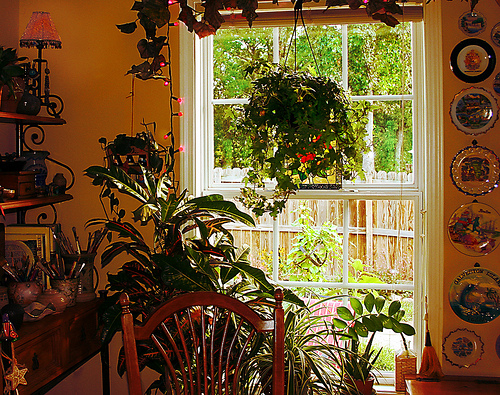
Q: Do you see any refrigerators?
A: No, there are no refrigerators.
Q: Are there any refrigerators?
A: No, there are no refrigerators.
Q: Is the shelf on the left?
A: Yes, the shelf is on the left of the image.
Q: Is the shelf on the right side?
A: No, the shelf is on the left of the image.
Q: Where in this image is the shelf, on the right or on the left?
A: The shelf is on the left of the image.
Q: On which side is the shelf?
A: The shelf is on the left of the image.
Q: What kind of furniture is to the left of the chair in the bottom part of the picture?
A: The piece of furniture is a shelf.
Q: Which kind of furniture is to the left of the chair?
A: The piece of furniture is a shelf.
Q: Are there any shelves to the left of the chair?
A: Yes, there is a shelf to the left of the chair.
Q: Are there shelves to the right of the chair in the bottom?
A: No, the shelf is to the left of the chair.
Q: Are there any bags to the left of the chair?
A: No, there is a shelf to the left of the chair.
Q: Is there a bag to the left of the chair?
A: No, there is a shelf to the left of the chair.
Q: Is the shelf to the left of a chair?
A: Yes, the shelf is to the left of a chair.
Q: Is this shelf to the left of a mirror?
A: No, the shelf is to the left of a chair.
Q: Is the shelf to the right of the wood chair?
A: No, the shelf is to the left of the chair.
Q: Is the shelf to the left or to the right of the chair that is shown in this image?
A: The shelf is to the left of the chair.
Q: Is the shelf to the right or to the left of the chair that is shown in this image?
A: The shelf is to the left of the chair.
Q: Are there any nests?
A: No, there are no nests.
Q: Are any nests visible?
A: No, there are no nests.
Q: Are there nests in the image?
A: No, there are no nests.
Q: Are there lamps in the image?
A: Yes, there is a lamp.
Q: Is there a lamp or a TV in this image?
A: Yes, there is a lamp.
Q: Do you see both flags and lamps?
A: No, there is a lamp but no flags.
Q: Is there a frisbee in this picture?
A: No, there are no frisbees.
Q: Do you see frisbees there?
A: No, there are no frisbees.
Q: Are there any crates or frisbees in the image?
A: No, there are no frisbees or crates.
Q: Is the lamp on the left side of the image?
A: Yes, the lamp is on the left of the image.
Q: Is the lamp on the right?
A: No, the lamp is on the left of the image.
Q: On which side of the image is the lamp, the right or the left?
A: The lamp is on the left of the image.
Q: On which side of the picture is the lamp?
A: The lamp is on the left of the image.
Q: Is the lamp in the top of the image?
A: Yes, the lamp is in the top of the image.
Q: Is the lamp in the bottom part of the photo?
A: No, the lamp is in the top of the image.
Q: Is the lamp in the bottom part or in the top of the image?
A: The lamp is in the top of the image.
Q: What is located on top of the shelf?
A: The lamp is on top of the shelf.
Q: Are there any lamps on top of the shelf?
A: Yes, there is a lamp on top of the shelf.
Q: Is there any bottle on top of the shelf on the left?
A: No, there is a lamp on top of the shelf.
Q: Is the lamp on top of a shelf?
A: Yes, the lamp is on top of a shelf.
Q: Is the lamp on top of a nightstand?
A: No, the lamp is on top of a shelf.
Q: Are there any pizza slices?
A: No, there are no pizza slices.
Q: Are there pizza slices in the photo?
A: No, there are no pizza slices.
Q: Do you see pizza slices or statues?
A: No, there are no pizza slices or statues.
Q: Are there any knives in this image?
A: No, there are no knives.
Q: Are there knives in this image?
A: No, there are no knives.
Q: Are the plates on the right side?
A: Yes, the plates are on the right of the image.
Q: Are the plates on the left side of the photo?
A: No, the plates are on the right of the image.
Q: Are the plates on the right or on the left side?
A: The plates are on the right of the image.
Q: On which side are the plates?
A: The plates are on the right of the image.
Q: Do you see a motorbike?
A: No, there are no motorcycles.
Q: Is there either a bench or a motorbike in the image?
A: No, there are no motorcycles or benches.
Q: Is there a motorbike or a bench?
A: No, there are no motorcycles or benches.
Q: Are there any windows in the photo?
A: Yes, there is a window.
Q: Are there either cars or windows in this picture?
A: Yes, there is a window.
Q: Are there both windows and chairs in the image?
A: Yes, there are both a window and a chair.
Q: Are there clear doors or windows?
A: Yes, there is a clear window.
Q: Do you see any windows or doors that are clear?
A: Yes, the window is clear.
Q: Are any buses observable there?
A: No, there are no buses.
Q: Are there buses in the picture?
A: No, there are no buses.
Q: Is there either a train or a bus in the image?
A: No, there are no buses or trains.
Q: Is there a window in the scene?
A: Yes, there is a window.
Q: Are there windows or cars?
A: Yes, there is a window.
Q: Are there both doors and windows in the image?
A: Yes, there are both a window and a door.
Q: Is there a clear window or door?
A: Yes, there is a clear window.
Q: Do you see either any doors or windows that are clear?
A: Yes, the window is clear.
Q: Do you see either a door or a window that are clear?
A: Yes, the window is clear.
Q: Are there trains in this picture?
A: No, there are no trains.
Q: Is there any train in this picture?
A: No, there are no trains.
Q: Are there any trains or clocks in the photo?
A: No, there are no trains or clocks.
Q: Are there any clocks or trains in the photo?
A: No, there are no trains or clocks.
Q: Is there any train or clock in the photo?
A: No, there are no trains or clocks.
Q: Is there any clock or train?
A: No, there are no trains or clocks.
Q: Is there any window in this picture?
A: Yes, there is a window.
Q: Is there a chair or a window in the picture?
A: Yes, there is a window.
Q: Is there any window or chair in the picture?
A: Yes, there is a window.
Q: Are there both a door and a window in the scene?
A: Yes, there are both a window and a door.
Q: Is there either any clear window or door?
A: Yes, there is a clear window.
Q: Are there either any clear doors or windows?
A: Yes, there is a clear window.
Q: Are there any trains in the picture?
A: No, there are no trains.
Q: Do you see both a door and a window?
A: Yes, there are both a window and a door.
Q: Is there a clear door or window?
A: Yes, there is a clear window.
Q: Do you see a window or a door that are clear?
A: Yes, the window is clear.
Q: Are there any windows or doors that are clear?
A: Yes, the window is clear.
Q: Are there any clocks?
A: No, there are no clocks.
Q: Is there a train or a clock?
A: No, there are no clocks or trains.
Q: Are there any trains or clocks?
A: No, there are no clocks or trains.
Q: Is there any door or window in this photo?
A: Yes, there is a window.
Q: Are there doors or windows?
A: Yes, there is a window.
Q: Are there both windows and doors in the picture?
A: Yes, there are both a window and a door.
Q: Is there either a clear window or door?
A: Yes, there is a clear window.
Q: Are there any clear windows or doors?
A: Yes, there is a clear window.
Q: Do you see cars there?
A: No, there are no cars.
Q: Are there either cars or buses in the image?
A: No, there are no cars or buses.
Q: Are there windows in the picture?
A: Yes, there is a window.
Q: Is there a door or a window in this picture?
A: Yes, there is a window.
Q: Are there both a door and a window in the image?
A: Yes, there are both a window and a door.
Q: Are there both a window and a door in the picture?
A: Yes, there are both a window and a door.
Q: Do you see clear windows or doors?
A: Yes, there is a clear window.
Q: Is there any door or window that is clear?
A: Yes, the window is clear.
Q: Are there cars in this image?
A: No, there are no cars.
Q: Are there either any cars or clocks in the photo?
A: No, there are no cars or clocks.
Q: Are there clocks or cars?
A: No, there are no cars or clocks.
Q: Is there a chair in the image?
A: Yes, there is a chair.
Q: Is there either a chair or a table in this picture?
A: Yes, there is a chair.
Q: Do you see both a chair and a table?
A: Yes, there are both a chair and a table.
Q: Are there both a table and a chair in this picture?
A: Yes, there are both a chair and a table.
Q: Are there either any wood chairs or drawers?
A: Yes, there is a wood chair.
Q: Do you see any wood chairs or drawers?
A: Yes, there is a wood chair.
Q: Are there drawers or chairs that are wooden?
A: Yes, the chair is wooden.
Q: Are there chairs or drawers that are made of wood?
A: Yes, the chair is made of wood.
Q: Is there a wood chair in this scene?
A: Yes, there is a wood chair.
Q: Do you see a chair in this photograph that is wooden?
A: Yes, there is a chair that is wooden.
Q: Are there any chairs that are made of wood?
A: Yes, there is a chair that is made of wood.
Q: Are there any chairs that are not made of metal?
A: Yes, there is a chair that is made of wood.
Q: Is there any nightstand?
A: No, there are no nightstands.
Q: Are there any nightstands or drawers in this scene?
A: No, there are no nightstands or drawers.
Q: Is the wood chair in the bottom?
A: Yes, the chair is in the bottom of the image.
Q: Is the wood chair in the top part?
A: No, the chair is in the bottom of the image.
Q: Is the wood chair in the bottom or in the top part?
A: The chair is in the bottom of the image.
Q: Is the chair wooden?
A: Yes, the chair is wooden.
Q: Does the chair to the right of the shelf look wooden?
A: Yes, the chair is wooden.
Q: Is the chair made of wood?
A: Yes, the chair is made of wood.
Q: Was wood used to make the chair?
A: Yes, the chair is made of wood.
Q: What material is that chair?
A: The chair is made of wood.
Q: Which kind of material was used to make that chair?
A: The chair is made of wood.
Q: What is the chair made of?
A: The chair is made of wood.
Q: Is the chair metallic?
A: No, the chair is wooden.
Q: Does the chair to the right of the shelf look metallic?
A: No, the chair is wooden.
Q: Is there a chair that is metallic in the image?
A: No, there is a chair but it is wooden.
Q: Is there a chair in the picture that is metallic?
A: No, there is a chair but it is wooden.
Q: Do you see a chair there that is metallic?
A: No, there is a chair but it is wooden.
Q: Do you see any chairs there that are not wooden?
A: No, there is a chair but it is wooden.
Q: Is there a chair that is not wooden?
A: No, there is a chair but it is wooden.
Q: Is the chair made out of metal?
A: No, the chair is made of wood.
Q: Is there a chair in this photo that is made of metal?
A: No, there is a chair but it is made of wood.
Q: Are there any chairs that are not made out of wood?
A: No, there is a chair but it is made of wood.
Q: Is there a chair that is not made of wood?
A: No, there is a chair but it is made of wood.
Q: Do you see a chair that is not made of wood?
A: No, there is a chair but it is made of wood.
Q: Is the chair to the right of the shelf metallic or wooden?
A: The chair is wooden.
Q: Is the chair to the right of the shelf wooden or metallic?
A: The chair is wooden.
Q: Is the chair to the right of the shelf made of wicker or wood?
A: The chair is made of wood.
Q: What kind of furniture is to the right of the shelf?
A: The piece of furniture is a chair.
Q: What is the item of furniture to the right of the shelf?
A: The piece of furniture is a chair.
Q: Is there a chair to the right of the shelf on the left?
A: Yes, there is a chair to the right of the shelf.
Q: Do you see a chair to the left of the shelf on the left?
A: No, the chair is to the right of the shelf.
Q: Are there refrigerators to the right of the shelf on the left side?
A: No, there is a chair to the right of the shelf.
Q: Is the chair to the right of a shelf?
A: Yes, the chair is to the right of a shelf.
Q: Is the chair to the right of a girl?
A: No, the chair is to the right of a shelf.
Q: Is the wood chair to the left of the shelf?
A: No, the chair is to the right of the shelf.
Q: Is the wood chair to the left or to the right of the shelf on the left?
A: The chair is to the right of the shelf.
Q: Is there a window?
A: Yes, there is a window.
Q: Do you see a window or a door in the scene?
A: Yes, there is a window.